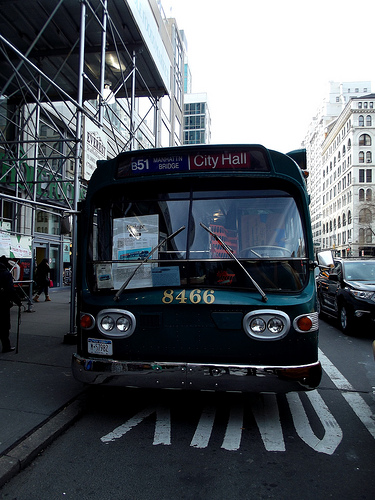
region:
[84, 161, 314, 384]
bus is black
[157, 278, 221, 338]
gold numbers on front of bus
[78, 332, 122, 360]
blue and white license plate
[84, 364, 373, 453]
white letters on road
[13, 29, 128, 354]
steel beams beside bus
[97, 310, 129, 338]
clear headlights on bus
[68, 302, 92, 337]
read headlight on bus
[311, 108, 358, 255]
grey building in background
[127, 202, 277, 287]
windshield wipers are black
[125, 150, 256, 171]
bus destination on red and blue sign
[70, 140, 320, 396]
old school bus on street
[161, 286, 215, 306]
bus has number 8466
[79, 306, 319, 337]
lights on bus front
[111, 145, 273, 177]
sign says city hall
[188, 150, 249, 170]
half of sign is red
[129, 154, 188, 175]
half of sign is blue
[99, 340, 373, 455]
white paint markings on street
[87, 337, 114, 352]
license plate on bus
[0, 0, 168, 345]
metal rafters under awning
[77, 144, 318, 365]
bus is shiny and green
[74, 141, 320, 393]
A GREEN CITY BUS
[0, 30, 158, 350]
Scaffolding for building construction above the sidewalk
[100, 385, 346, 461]
"ONLY" painted on the street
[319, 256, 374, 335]
a black sedan car driving on the street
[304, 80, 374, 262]
a multi-story city building on the side of the street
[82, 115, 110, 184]
a sign on the scaffold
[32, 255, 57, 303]
a woman dressed in a winter coat and boots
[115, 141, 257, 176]
The bus route sign on the front of the bus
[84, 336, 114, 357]
The bus' New York license plate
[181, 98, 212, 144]
a tall glass building in the background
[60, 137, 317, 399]
a dark green bus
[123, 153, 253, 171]
bus destination sign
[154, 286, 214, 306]
a bus number 8466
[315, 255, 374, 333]
a dark colored minivan in street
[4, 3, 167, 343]
large metal scaffolding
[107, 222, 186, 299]
a bus right windshield wiper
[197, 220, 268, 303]
a bus left windshield wiper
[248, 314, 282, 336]
a bus' front left headlights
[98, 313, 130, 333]
a bus' front right headlights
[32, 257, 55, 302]
a pedestrian on sidewalk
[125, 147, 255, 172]
destination sign on front of bus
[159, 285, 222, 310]
identification number at front of bus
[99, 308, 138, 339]
headlight at front of bus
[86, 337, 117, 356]
license plate at front of bus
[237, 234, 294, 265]
steering wheel on bus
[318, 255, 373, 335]
car in traffic on busy city street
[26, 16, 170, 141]
scaffolding outside of building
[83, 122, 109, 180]
sign on scaffolding outside of building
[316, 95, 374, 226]
building on busy city street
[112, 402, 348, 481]
"turn lane only" warning on city street